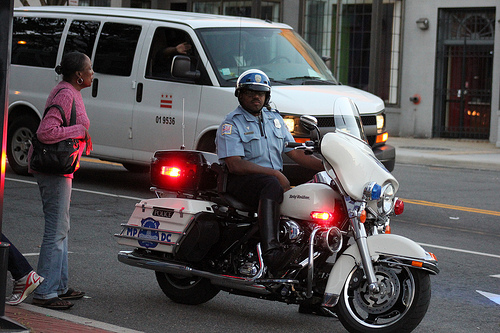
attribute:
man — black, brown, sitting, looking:
[214, 62, 328, 247]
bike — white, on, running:
[131, 125, 418, 331]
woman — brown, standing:
[29, 34, 104, 307]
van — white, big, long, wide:
[10, 2, 399, 195]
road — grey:
[3, 126, 499, 331]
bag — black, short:
[34, 104, 80, 172]